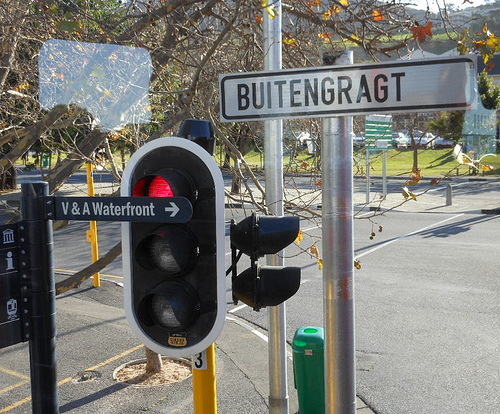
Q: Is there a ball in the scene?
A: No, there are no balls.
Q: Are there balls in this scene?
A: No, there are no balls.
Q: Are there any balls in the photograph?
A: No, there are no balls.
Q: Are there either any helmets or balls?
A: No, there are no balls or helmets.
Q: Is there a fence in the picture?
A: No, there are no fences.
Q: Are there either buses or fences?
A: No, there are no fences or buses.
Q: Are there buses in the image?
A: No, there are no buses.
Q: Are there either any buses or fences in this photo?
A: No, there are no buses or fences.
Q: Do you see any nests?
A: No, there are no nests.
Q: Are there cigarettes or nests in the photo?
A: No, there are no nests or cigarettes.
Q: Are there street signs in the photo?
A: Yes, there is a street sign.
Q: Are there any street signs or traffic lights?
A: Yes, there is a street sign.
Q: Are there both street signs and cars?
A: Yes, there are both a street sign and a car.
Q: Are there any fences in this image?
A: No, there are no fences.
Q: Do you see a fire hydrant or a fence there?
A: No, there are no fences or fire hydrants.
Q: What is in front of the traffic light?
A: The street sign is in front of the signal light.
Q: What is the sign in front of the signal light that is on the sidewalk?
A: The sign is a street sign.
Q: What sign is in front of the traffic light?
A: The sign is a street sign.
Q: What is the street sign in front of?
A: The street sign is in front of the traffic light.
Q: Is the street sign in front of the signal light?
A: Yes, the street sign is in front of the signal light.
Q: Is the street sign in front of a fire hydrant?
A: No, the street sign is in front of the signal light.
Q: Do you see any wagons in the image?
A: No, there are no wagons.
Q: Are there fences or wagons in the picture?
A: No, there are no wagons or fences.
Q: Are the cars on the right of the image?
A: Yes, the cars are on the right of the image.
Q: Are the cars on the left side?
A: No, the cars are on the right of the image.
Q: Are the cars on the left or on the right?
A: The cars are on the right of the image.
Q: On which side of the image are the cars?
A: The cars are on the right of the image.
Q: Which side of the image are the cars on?
A: The cars are on the right of the image.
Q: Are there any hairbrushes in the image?
A: No, there are no hairbrushes.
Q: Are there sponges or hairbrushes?
A: No, there are no hairbrushes or sponges.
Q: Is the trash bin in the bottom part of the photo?
A: Yes, the trash bin is in the bottom of the image.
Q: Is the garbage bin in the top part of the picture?
A: No, the garbage bin is in the bottom of the image.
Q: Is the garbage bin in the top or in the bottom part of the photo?
A: The garbage bin is in the bottom of the image.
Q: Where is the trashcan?
A: The trashcan is on the sidewalk.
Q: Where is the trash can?
A: The trashcan is on the sidewalk.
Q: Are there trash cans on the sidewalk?
A: Yes, there is a trash can on the sidewalk.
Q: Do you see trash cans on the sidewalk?
A: Yes, there is a trash can on the sidewalk.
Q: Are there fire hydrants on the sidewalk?
A: No, there is a trash can on the sidewalk.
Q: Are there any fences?
A: No, there are no fences.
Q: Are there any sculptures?
A: No, there are no sculptures.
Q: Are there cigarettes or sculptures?
A: No, there are no sculptures or cigarettes.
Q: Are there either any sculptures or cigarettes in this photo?
A: No, there are no sculptures or cigarettes.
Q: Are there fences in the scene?
A: No, there are no fences.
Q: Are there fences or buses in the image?
A: No, there are no fences or buses.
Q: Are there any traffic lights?
A: Yes, there is a traffic light.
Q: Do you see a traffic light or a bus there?
A: Yes, there is a traffic light.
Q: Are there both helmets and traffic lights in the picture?
A: No, there is a traffic light but no helmets.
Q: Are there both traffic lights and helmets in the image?
A: No, there is a traffic light but no helmets.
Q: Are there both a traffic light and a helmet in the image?
A: No, there is a traffic light but no helmets.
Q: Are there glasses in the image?
A: No, there are no glasses.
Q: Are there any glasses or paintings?
A: No, there are no glasses or paintings.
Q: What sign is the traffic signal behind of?
A: The traffic signal is behind the street sign.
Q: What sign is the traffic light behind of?
A: The traffic signal is behind the street sign.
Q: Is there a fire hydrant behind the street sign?
A: No, there is a traffic light behind the street sign.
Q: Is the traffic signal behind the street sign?
A: Yes, the traffic signal is behind the street sign.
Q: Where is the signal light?
A: The signal light is on the side walk.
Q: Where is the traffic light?
A: The signal light is on the side walk.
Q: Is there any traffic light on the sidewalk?
A: Yes, there is a traffic light on the sidewalk.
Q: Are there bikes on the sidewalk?
A: No, there is a traffic light on the sidewalk.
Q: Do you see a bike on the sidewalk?
A: No, there is a traffic light on the sidewalk.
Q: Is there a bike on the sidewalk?
A: No, there is a traffic light on the sidewalk.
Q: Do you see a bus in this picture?
A: No, there are no buses.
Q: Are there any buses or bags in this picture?
A: No, there are no buses or bags.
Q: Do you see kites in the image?
A: No, there are no kites.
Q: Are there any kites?
A: No, there are no kites.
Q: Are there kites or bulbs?
A: No, there are no kites or bulbs.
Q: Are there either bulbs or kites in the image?
A: No, there are no kites or bulbs.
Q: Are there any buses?
A: No, there are no buses.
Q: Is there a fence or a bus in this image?
A: No, there are no buses or fences.